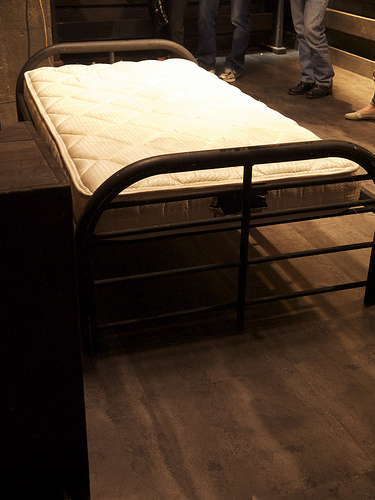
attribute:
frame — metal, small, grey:
[17, 31, 374, 345]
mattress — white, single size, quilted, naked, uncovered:
[19, 54, 373, 230]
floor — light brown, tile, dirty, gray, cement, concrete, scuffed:
[1, 48, 374, 499]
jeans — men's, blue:
[288, 2, 335, 81]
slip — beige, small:
[355, 112, 363, 122]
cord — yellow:
[37, 4, 57, 64]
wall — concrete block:
[0, 5, 50, 116]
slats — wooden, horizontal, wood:
[298, 2, 374, 77]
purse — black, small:
[143, 1, 172, 32]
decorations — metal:
[150, 2, 172, 24]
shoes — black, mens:
[285, 76, 334, 104]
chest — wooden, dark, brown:
[3, 119, 94, 500]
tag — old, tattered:
[211, 188, 266, 218]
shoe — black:
[302, 80, 333, 99]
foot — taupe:
[341, 105, 375, 124]